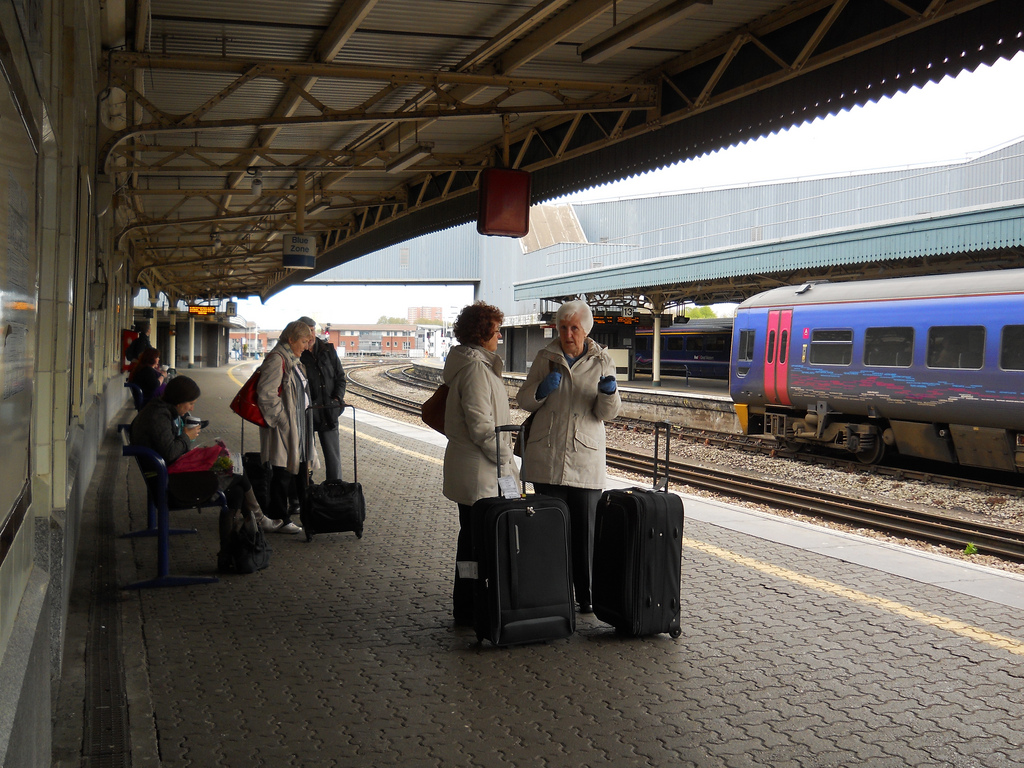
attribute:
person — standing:
[532, 296, 610, 603]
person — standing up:
[286, 305, 350, 506]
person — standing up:
[244, 296, 317, 537]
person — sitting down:
[127, 380, 248, 516]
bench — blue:
[121, 391, 214, 581]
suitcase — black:
[468, 484, 561, 628]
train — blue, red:
[738, 292, 1008, 469]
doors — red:
[759, 301, 778, 393]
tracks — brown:
[343, 361, 1002, 568]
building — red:
[228, 315, 428, 347]